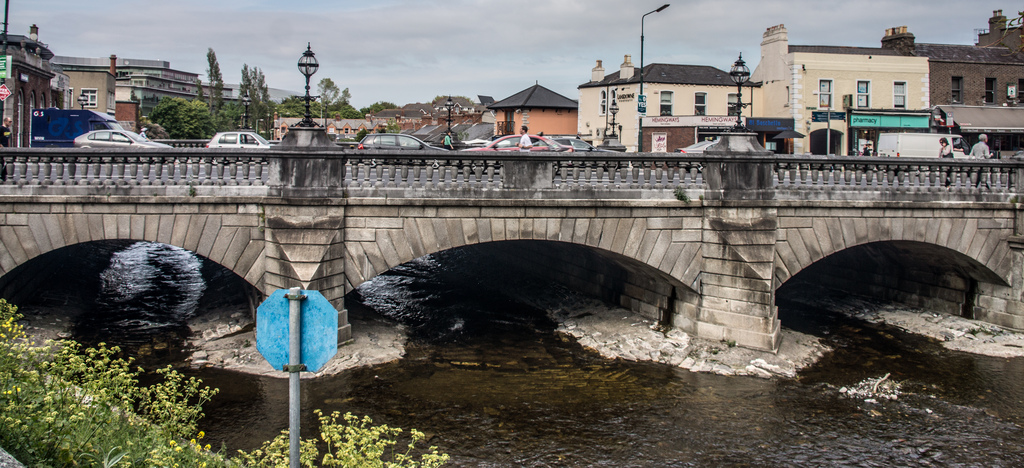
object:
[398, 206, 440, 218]
stone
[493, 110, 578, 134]
wall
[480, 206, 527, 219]
stone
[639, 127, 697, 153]
wall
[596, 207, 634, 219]
stone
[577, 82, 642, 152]
wall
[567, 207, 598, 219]
stone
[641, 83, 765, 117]
wall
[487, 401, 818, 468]
water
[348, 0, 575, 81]
sky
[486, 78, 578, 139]
building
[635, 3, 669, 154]
street lamp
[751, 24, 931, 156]
building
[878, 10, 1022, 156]
building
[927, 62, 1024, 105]
wall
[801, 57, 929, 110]
wall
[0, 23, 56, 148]
building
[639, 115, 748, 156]
building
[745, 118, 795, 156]
building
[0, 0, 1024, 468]
city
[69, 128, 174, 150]
car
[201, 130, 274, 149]
car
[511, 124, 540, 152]
person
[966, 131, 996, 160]
person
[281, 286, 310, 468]
pole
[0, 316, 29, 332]
yellow flowers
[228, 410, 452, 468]
bush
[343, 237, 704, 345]
dark alley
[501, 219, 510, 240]
wall partitions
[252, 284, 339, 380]
road sign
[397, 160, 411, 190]
wooden poles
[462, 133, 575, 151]
vehicles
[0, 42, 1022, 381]
bridge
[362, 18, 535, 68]
clouds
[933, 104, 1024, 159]
buildings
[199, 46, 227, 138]
trees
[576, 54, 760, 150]
building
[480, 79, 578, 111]
grey roof